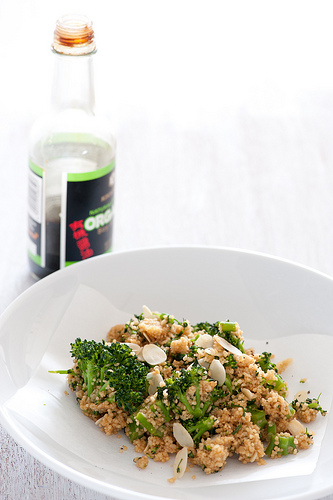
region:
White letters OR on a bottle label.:
[83, 214, 103, 231]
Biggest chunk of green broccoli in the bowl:
[68, 336, 147, 408]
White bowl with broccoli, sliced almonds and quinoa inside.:
[0, 245, 331, 499]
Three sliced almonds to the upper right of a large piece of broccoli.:
[122, 342, 166, 364]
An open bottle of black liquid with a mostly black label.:
[24, 12, 116, 280]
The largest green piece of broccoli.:
[72, 337, 147, 410]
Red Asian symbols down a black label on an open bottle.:
[68, 219, 94, 258]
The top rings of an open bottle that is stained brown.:
[53, 18, 96, 46]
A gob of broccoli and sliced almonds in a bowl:
[55, 305, 325, 482]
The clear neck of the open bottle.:
[51, 52, 96, 118]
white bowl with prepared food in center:
[4, 232, 326, 497]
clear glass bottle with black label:
[20, 7, 123, 281]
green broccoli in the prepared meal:
[68, 336, 148, 409]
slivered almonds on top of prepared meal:
[130, 324, 238, 392]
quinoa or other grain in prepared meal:
[183, 406, 272, 471]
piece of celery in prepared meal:
[273, 429, 298, 457]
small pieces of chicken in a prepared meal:
[137, 304, 192, 353]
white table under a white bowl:
[116, 115, 329, 281]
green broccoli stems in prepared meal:
[173, 381, 212, 417]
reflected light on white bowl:
[15, 294, 76, 471]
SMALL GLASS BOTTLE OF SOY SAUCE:
[30, 22, 124, 251]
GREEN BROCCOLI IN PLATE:
[79, 325, 283, 471]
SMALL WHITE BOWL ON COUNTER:
[29, 254, 317, 495]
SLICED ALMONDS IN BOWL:
[137, 340, 177, 371]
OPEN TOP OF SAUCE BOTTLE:
[39, 15, 107, 54]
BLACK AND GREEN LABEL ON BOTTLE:
[55, 175, 133, 260]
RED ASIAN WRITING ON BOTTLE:
[57, 220, 119, 266]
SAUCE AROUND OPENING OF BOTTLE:
[57, 29, 93, 47]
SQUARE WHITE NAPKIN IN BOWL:
[53, 302, 301, 498]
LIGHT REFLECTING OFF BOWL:
[22, 273, 266, 310]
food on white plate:
[57, 297, 329, 485]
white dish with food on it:
[5, 235, 331, 498]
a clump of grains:
[238, 435, 265, 466]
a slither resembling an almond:
[141, 342, 170, 363]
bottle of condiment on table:
[23, 2, 116, 285]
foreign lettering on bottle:
[68, 218, 95, 262]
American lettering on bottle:
[81, 188, 114, 232]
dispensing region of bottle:
[53, 11, 97, 31]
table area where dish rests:
[2, 459, 51, 498]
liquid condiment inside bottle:
[47, 214, 61, 269]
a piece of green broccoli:
[70, 335, 115, 392]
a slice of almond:
[138, 338, 168, 365]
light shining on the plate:
[1, 354, 69, 432]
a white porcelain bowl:
[0, 243, 332, 499]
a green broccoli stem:
[82, 365, 98, 397]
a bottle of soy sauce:
[16, 8, 120, 284]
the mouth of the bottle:
[55, 10, 99, 39]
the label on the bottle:
[19, 129, 117, 274]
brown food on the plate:
[233, 422, 271, 467]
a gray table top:
[0, 427, 116, 497]